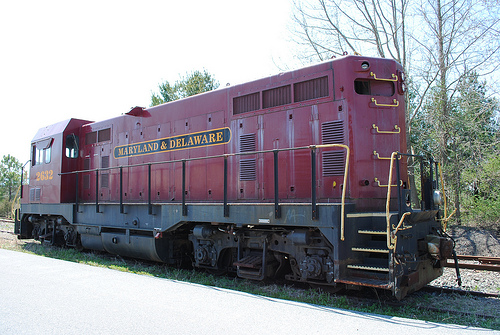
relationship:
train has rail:
[13, 56, 454, 304] [57, 145, 351, 243]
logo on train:
[112, 126, 232, 160] [13, 56, 454, 304]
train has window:
[13, 56, 454, 304] [293, 75, 329, 101]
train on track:
[13, 56, 454, 304] [2, 217, 500, 318]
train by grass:
[13, 56, 454, 304] [0, 238, 499, 331]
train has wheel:
[13, 56, 454, 304] [204, 246, 234, 275]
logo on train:
[35, 169, 55, 182] [13, 56, 454, 304]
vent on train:
[321, 119, 345, 145] [13, 56, 454, 304]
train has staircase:
[13, 56, 454, 304] [334, 212, 401, 290]